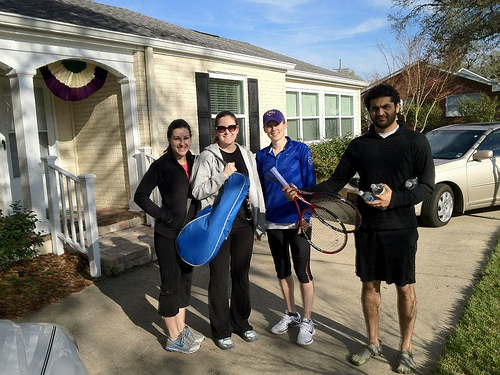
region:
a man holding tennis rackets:
[268, 82, 433, 369]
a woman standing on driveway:
[254, 107, 316, 347]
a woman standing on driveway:
[188, 108, 263, 349]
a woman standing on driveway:
[134, 116, 206, 354]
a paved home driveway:
[16, 182, 499, 374]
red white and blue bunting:
[41, 59, 108, 102]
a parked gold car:
[413, 120, 499, 230]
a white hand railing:
[37, 152, 103, 281]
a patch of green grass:
[438, 231, 498, 373]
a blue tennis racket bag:
[177, 171, 246, 271]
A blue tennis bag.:
[179, 152, 251, 265]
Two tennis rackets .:
[269, 164, 364, 254]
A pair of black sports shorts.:
[354, 229, 417, 284]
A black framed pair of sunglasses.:
[217, 122, 239, 133]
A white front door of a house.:
[3, 79, 80, 213]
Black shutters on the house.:
[197, 72, 261, 161]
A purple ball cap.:
[263, 109, 284, 125]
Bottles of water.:
[356, 179, 423, 210]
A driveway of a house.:
[1, 176, 496, 373]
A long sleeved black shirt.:
[302, 129, 434, 220]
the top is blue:
[256, 146, 330, 227]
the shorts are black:
[354, 228, 420, 278]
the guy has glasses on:
[205, 110, 276, 356]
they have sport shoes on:
[151, 316, 418, 373]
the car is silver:
[439, 118, 499, 231]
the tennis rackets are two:
[270, 143, 375, 281]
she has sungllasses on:
[208, 120, 260, 148]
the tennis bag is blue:
[186, 180, 264, 282]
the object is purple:
[51, 77, 128, 113]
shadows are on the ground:
[123, 279, 156, 317]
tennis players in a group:
[125, 112, 481, 364]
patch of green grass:
[466, 348, 481, 361]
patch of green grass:
[446, 358, 459, 372]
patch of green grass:
[478, 323, 489, 337]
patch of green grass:
[482, 290, 495, 303]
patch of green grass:
[473, 292, 484, 301]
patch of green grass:
[473, 363, 487, 370]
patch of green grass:
[477, 326, 490, 333]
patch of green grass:
[477, 279, 494, 289]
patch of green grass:
[480, 318, 496, 328]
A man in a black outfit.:
[283, 84, 435, 374]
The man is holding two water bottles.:
[354, 178, 398, 214]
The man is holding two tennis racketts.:
[269, 163, 363, 253]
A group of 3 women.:
[131, 108, 316, 355]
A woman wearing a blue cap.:
[254, 108, 316, 347]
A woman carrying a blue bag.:
[174, 110, 267, 350]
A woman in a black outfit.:
[131, 116, 205, 356]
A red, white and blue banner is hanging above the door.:
[35, 44, 110, 103]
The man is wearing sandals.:
[347, 338, 421, 374]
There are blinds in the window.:
[207, 78, 240, 115]